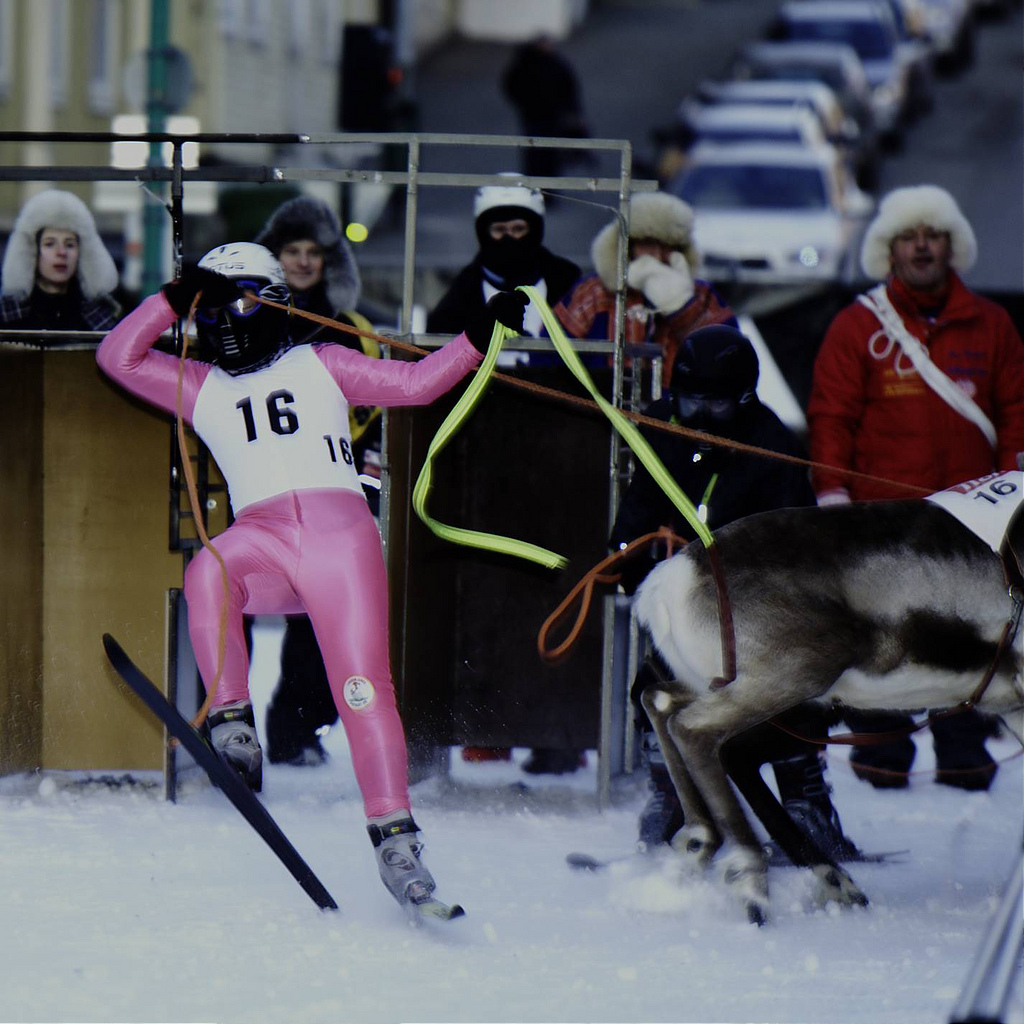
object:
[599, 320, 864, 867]
person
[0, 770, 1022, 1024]
ice